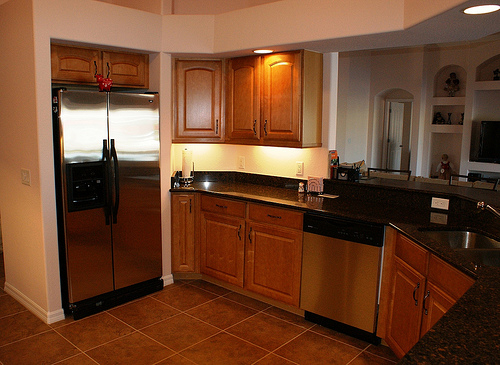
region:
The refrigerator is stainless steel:
[70, 103, 159, 278]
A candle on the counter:
[180, 152, 205, 193]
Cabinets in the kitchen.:
[186, 61, 308, 128]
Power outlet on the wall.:
[292, 149, 308, 177]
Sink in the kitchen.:
[438, 206, 498, 260]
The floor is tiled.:
[151, 300, 234, 352]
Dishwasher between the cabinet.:
[306, 210, 381, 352]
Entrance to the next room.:
[361, 81, 418, 168]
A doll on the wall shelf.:
[433, 140, 449, 178]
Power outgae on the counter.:
[426, 191, 456, 216]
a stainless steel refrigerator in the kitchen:
[53, 85, 163, 322]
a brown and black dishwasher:
[298, 211, 383, 333]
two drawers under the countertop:
[199, 195, 305, 230]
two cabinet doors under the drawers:
[196, 213, 302, 307]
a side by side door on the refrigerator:
[57, 88, 164, 323]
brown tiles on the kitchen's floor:
[135, 300, 258, 362]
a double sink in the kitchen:
[415, 226, 498, 268]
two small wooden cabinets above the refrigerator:
[52, 46, 149, 89]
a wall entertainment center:
[465, 50, 499, 175]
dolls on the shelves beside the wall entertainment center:
[428, 64, 467, 179]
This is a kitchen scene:
[1, 0, 498, 363]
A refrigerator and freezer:
[51, 85, 164, 322]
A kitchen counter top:
[171, 167, 498, 363]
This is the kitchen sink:
[416, 201, 498, 276]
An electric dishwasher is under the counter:
[299, 207, 385, 347]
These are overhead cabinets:
[171, 46, 326, 148]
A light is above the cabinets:
[250, 42, 275, 58]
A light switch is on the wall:
[18, 166, 31, 185]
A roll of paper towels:
[181, 148, 193, 180]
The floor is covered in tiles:
[0, 277, 398, 364]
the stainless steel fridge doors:
[59, 83, 159, 311]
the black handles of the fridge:
[102, 130, 122, 232]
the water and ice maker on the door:
[65, 158, 105, 206]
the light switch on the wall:
[17, 169, 37, 193]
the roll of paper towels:
[177, 147, 191, 189]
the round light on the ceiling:
[251, 46, 271, 56]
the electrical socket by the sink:
[422, 193, 452, 214]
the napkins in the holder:
[308, 176, 323, 196]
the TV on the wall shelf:
[469, 112, 499, 161]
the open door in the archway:
[380, 97, 413, 171]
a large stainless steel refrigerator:
[52, 80, 164, 310]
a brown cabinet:
[170, 54, 222, 142]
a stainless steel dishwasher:
[299, 210, 379, 330]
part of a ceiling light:
[462, 3, 496, 20]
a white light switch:
[15, 165, 38, 182]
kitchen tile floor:
[0, 283, 391, 364]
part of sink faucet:
[469, 198, 496, 219]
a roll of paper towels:
[180, 147, 192, 175]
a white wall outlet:
[429, 198, 454, 212]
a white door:
[386, 103, 407, 169]